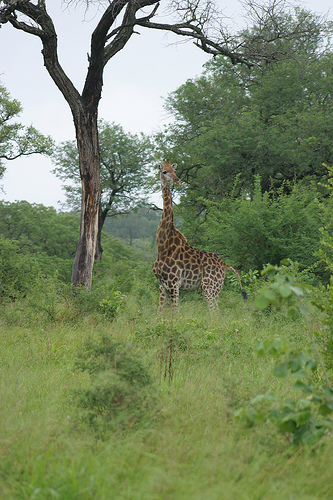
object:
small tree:
[48, 117, 162, 264]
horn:
[162, 158, 165, 162]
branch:
[135, 17, 256, 69]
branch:
[102, 0, 160, 61]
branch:
[0, 7, 42, 37]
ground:
[0, 266, 333, 500]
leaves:
[268, 90, 299, 144]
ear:
[171, 163, 178, 170]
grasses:
[0, 436, 228, 500]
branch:
[0, 110, 19, 124]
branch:
[0, 150, 48, 161]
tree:
[0, 84, 58, 204]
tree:
[162, 9, 333, 243]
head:
[158, 159, 181, 186]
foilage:
[156, 323, 191, 389]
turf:
[241, 289, 248, 300]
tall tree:
[0, 0, 264, 293]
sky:
[0, 2, 109, 93]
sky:
[0, 154, 65, 210]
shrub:
[68, 331, 158, 448]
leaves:
[252, 292, 271, 310]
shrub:
[226, 255, 333, 471]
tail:
[224, 264, 248, 301]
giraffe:
[152, 158, 248, 323]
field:
[1, 236, 331, 498]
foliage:
[5, 225, 54, 328]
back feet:
[211, 315, 220, 320]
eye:
[162, 170, 167, 175]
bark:
[86, 189, 97, 219]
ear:
[158, 163, 163, 169]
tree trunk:
[70, 108, 102, 294]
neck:
[161, 184, 174, 227]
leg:
[170, 280, 180, 319]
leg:
[155, 277, 167, 317]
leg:
[203, 285, 221, 317]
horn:
[167, 157, 169, 161]